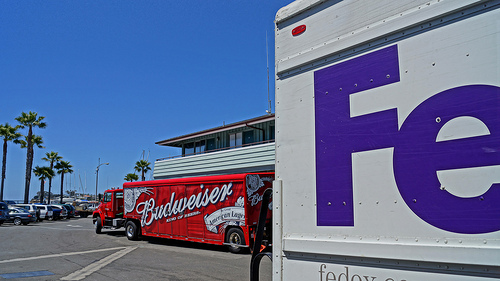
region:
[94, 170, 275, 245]
a red truck.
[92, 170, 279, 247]
a Budweiser truck.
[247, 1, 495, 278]
a Fedex truck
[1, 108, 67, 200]
six tall palm trees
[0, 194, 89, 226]
a line of parked cars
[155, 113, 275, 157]
an office building.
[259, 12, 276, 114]
an antenna on top of a building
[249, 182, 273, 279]
a black door handle attached to the back of a truck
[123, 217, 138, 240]
a big truck tire .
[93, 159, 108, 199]
a light pole.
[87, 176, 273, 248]
Beer truck in parking lot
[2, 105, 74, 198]
Six palm trees against blue sky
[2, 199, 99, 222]
Cars in a parkiang lot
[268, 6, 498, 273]
Fedex delivery truck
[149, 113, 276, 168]
Building behind beer truck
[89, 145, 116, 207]
Street light near parking lot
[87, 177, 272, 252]
Red Budweiser truck near Fedex truck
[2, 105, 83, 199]
Palm trees in the bright sun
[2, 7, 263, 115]
No clouds in the sky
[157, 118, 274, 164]
Hotel beside parking lot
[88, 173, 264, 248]
A red truck in the photo.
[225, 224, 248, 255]
A wheel in the photo.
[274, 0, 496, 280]
A white truck in the photo.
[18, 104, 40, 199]
A tree in the photo.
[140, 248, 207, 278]
A road with tarmac.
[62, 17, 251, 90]
Blue skies in the photo.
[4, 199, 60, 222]
Cars in the parking.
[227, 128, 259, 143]
Windows in the photo.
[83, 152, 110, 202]
A street light in the photo.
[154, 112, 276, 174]
A building in the photo.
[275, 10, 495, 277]
Side of large truck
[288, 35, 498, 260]
Side of white truck with letters Fe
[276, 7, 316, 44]
Reflector on side of white truck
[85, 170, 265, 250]
Large red semi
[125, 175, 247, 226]
The word Budweiser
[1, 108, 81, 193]
A group of palm trees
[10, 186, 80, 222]
A parking lot of cars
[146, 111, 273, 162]
A tall building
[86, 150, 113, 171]
A street light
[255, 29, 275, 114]
A tall antenna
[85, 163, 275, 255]
a red truck with white letters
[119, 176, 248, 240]
letters on truck says "Budweiser"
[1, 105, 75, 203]
palms on side a parking lot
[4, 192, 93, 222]
cars parking on side parking lot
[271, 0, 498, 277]
part of a truck with blue letters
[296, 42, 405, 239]
letter F on a truck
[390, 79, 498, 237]
letter e on a truck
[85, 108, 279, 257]
a truck in front a building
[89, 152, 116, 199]
a light pole on the background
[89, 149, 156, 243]
two pines behind a truck